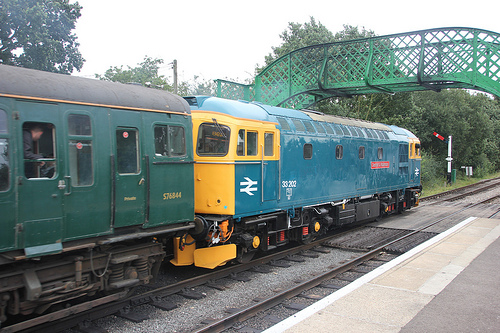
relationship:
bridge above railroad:
[212, 27, 498, 111] [29, 168, 499, 323]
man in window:
[22, 121, 45, 164] [18, 116, 59, 189]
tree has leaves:
[0, 0, 86, 74] [0, 0, 85, 75]